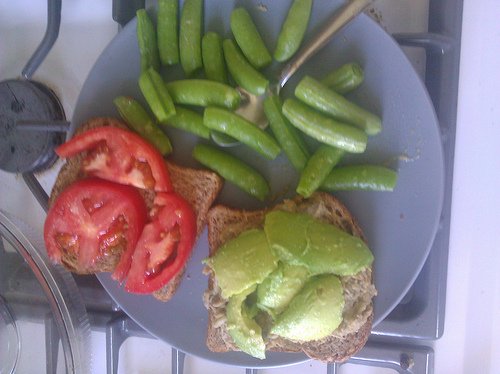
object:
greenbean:
[203, 105, 281, 159]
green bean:
[187, 137, 272, 201]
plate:
[46, 0, 444, 372]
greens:
[202, 108, 276, 158]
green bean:
[199, 30, 226, 80]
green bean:
[181, 2, 205, 72]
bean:
[135, 9, 159, 75]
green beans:
[268, 0, 311, 63]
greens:
[139, 63, 174, 121]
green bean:
[136, 68, 175, 118]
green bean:
[292, 145, 341, 199]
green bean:
[293, 73, 383, 137]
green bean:
[271, 0, 311, 64]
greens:
[113, 93, 169, 163]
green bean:
[192, 141, 269, 202]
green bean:
[260, 94, 313, 170]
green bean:
[138, 62, 178, 123]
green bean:
[229, 7, 272, 68]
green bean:
[317, 166, 397, 197]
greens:
[281, 95, 370, 157]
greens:
[161, 74, 238, 111]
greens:
[192, 147, 267, 202]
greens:
[230, 6, 270, 68]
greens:
[222, 5, 268, 66]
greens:
[190, 142, 270, 200]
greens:
[280, 97, 368, 153]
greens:
[136, 67, 174, 120]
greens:
[135, 7, 158, 69]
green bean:
[220, 36, 270, 96]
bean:
[295, 144, 343, 199]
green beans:
[291, 133, 347, 198]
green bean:
[265, 97, 367, 154]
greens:
[191, 149, 270, 198]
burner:
[1, 1, 463, 372]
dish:
[66, 0, 446, 370]